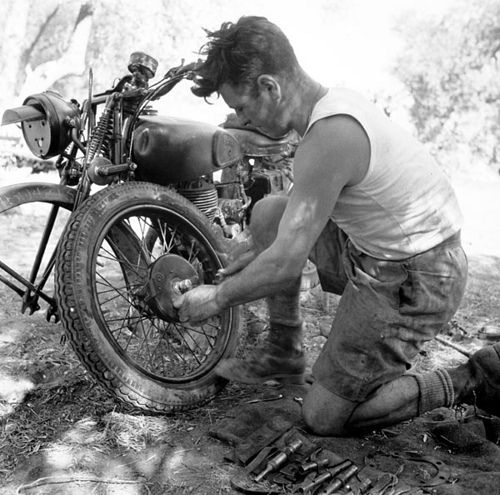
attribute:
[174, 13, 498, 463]
man — dirty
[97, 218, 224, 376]
spikes — metal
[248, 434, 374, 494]
tools — man's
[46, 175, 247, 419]
tire — worn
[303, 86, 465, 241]
shirt — sleeveless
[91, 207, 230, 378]
wheel spokes — pictured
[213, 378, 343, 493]
tools — metal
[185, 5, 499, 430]
man — pictured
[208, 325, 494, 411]
boots — dusty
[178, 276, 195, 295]
bolt — metal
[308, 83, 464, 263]
tank top — white